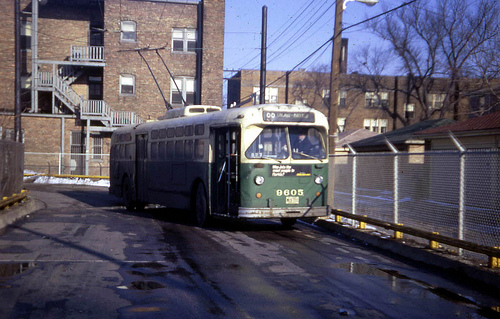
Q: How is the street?
A: Wet.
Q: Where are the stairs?
A: In building.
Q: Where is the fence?
A: Next to bus.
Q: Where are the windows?
A: On building.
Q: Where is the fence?
A: Front of building.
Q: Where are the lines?
A: On pole.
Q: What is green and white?
A: Bus.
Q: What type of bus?
A: Transit.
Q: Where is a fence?
A: Next to the bus.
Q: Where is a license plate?
A: On front of the bus.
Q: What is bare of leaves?
A: Trees.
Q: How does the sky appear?
A: Blue and clear.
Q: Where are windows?
A: On a building.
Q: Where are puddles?
A: On the ground.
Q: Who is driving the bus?
A: A bus driver.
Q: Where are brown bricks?
A: On building.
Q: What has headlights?
A: The bus.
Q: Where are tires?
A: On the bus.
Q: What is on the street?
A: A passenger bus is on the street.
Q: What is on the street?
A: A green passenger bus is on the street.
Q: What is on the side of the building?
A: Stairs are on the side of the building.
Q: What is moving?
A: The bus is moving.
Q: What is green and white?
A: The bus is green and white.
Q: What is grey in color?
A: The fence is grey.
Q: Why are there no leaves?
A: The season is winter.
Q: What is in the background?
A: A building.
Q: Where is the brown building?
A: Behind the bus.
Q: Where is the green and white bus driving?
A: On the road.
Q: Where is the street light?
A: On a brown wooden pole.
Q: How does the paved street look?
A: Black and wet.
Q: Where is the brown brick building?
A: Behind the green bus.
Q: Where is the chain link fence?
A: Next to the road.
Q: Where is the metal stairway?
A: On side of brick apartment building.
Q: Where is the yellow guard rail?
A: On side of road.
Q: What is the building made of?
A: Brick.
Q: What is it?
A: Trolley.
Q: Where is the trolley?
A: On the road.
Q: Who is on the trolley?
A: People.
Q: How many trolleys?
A: 1.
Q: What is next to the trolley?
A: Fence.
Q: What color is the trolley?
A: Green.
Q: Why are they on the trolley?
A: To get somewhere.